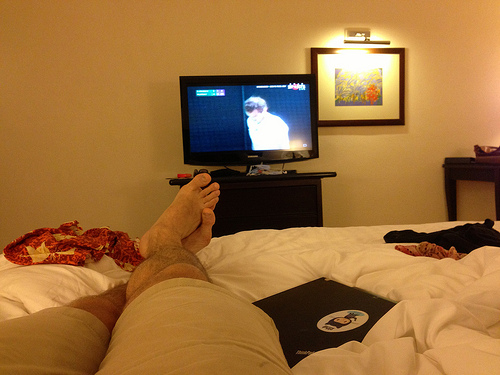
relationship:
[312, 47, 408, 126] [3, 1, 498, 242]
painting on wall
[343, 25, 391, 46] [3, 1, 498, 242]
light on wall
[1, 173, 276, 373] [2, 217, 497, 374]
person on bedf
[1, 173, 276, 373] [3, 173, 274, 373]
person has legs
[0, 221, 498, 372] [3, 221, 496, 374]
blanket on bed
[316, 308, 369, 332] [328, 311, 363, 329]
sticker has girl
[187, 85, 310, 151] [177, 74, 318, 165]
tennis on television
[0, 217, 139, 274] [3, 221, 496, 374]
clothing on bed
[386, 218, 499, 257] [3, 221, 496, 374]
clothing on bed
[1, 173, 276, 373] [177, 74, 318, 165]
person watching television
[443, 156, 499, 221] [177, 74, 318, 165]
table beside television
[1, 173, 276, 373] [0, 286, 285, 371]
person wearing shorts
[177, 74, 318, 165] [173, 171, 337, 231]
television on stand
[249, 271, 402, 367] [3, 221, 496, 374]
laptop on bed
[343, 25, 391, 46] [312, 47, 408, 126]
light above painting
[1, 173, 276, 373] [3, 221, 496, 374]
person on bed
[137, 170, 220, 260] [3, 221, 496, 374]
feet are on bed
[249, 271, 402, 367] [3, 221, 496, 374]
book on bed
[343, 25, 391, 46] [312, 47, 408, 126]
light abovie painting